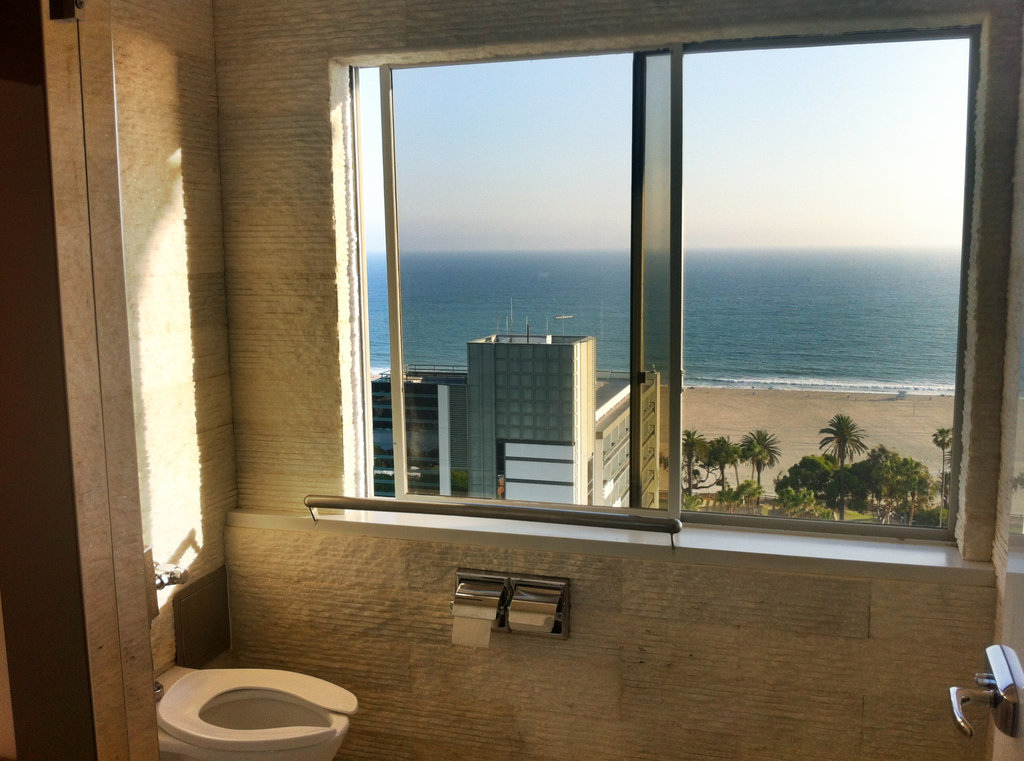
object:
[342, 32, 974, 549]
window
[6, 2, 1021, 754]
bathroom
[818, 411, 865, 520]
tree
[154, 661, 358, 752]
seat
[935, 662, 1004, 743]
handle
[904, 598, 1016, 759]
door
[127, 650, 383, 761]
toilet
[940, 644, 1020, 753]
silver handle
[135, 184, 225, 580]
sunlight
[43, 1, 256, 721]
wall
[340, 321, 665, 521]
building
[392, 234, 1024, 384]
water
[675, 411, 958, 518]
green/tall trees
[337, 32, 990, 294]
sky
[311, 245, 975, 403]
ocean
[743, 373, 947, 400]
foam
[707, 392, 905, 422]
sand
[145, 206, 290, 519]
ray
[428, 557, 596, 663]
holder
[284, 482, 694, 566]
rail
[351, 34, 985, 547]
sill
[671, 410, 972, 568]
palm trees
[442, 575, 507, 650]
rolls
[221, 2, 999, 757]
wall